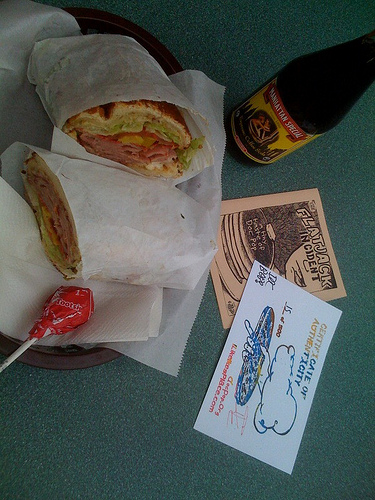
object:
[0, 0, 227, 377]
paper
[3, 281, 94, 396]
tootsie pop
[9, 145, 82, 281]
sandwich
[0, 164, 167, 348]
napkin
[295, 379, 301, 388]
letters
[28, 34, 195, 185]
sahdwich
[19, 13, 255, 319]
sandwich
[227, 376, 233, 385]
letters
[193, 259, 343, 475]
card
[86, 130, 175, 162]
ham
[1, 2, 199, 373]
brown plate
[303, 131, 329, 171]
ground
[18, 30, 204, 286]
cut sandwich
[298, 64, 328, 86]
ground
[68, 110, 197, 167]
sandwich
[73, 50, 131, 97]
paper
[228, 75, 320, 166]
label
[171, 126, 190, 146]
floor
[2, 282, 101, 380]
sucker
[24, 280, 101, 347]
red paper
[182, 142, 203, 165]
lettuce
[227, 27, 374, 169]
bottle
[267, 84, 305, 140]
writing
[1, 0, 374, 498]
table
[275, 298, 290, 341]
writing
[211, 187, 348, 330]
orange card